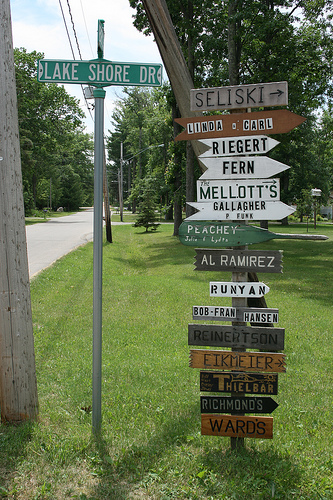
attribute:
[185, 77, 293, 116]
sign — wood, rectangular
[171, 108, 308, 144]
sign — arrow, brown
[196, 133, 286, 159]
sign — arrow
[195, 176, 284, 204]
sign — rectangular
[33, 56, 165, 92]
sign — green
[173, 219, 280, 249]
sign — green, wooden, oar-shaped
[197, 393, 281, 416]
sign — black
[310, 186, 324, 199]
bird house — white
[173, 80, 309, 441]
signs — labelled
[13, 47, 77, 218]
tree — green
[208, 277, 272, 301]
sign — small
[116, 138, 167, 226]
streetlight — metal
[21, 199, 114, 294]
road — paved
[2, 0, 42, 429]
pole — wooden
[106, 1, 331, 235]
trees — green